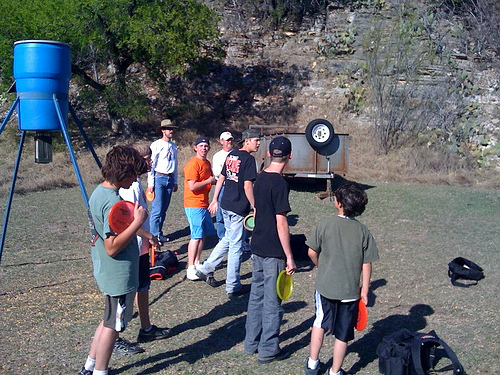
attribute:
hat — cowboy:
[156, 116, 179, 130]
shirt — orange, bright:
[182, 157, 213, 207]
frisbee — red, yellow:
[109, 200, 137, 238]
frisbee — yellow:
[277, 268, 293, 301]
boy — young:
[304, 182, 383, 374]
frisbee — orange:
[356, 297, 367, 331]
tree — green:
[0, 1, 231, 135]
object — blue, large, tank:
[1, 37, 106, 267]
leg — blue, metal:
[52, 90, 93, 210]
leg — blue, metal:
[68, 100, 102, 168]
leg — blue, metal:
[2, 133, 28, 257]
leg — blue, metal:
[1, 95, 17, 130]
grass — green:
[1, 180, 499, 371]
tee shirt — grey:
[303, 217, 379, 300]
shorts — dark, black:
[311, 292, 357, 340]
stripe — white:
[313, 292, 325, 331]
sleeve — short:
[270, 175, 291, 216]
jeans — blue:
[199, 209, 248, 291]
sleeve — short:
[185, 158, 200, 182]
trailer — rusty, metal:
[248, 120, 349, 198]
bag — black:
[446, 257, 484, 287]